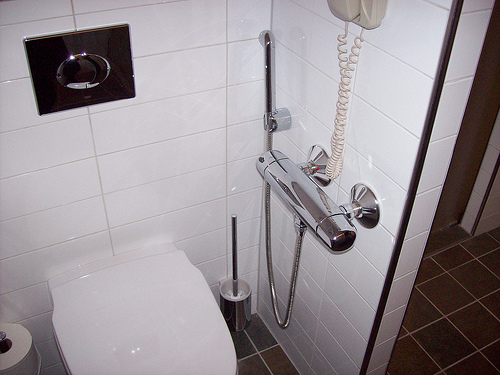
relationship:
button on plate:
[53, 49, 113, 94] [22, 20, 139, 117]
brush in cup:
[221, 278, 257, 338] [216, 274, 257, 330]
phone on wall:
[324, 15, 379, 182] [265, 21, 465, 373]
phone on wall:
[324, 15, 379, 182] [4, 7, 256, 321]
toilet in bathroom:
[21, 239, 252, 374] [3, 6, 491, 365]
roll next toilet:
[2, 317, 38, 371] [42, 242, 198, 368]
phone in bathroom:
[327, 0, 384, 30] [3, 6, 491, 365]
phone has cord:
[327, 0, 384, 30] [317, 15, 376, 183]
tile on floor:
[230, 223, 500, 375] [394, 216, 494, 370]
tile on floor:
[355, 31, 427, 146] [394, 216, 494, 370]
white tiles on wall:
[2, 0, 493, 373] [272, 0, 449, 373]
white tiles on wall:
[2, 0, 493, 373] [2, 1, 263, 372]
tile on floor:
[230, 223, 500, 375] [238, 248, 498, 366]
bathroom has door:
[3, 6, 491, 365] [393, 3, 495, 372]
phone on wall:
[327, 0, 384, 30] [258, 0, 493, 370]